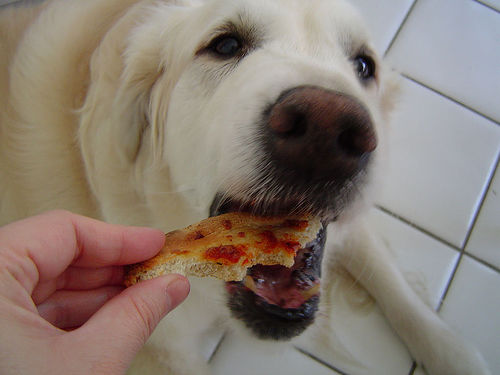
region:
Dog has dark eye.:
[193, 28, 255, 72]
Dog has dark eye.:
[338, 43, 383, 80]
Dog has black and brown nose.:
[295, 89, 354, 151]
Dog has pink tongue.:
[263, 273, 311, 325]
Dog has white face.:
[203, 106, 239, 156]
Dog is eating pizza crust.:
[183, 211, 268, 273]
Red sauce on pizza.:
[210, 240, 249, 268]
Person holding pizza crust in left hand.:
[72, 195, 189, 366]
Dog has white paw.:
[381, 299, 488, 371]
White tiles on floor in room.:
[416, 202, 463, 294]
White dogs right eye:
[350, 44, 380, 86]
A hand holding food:
[0, 210, 188, 372]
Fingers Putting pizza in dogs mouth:
[130, 193, 328, 340]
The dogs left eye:
[205, 28, 247, 66]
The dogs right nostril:
[335, 117, 365, 157]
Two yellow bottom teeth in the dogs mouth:
[245, 270, 320, 295]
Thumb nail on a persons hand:
[160, 275, 190, 305]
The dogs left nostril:
[276, 101, 307, 138]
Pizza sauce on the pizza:
[196, 219, 300, 271]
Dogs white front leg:
[390, 321, 493, 373]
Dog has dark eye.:
[197, 28, 244, 60]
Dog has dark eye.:
[343, 45, 387, 87]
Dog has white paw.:
[413, 309, 455, 362]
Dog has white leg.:
[346, 232, 370, 254]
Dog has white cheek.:
[191, 115, 221, 152]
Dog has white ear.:
[95, 46, 156, 111]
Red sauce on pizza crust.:
[208, 247, 255, 273]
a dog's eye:
[200, 28, 246, 61]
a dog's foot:
[353, 248, 491, 373]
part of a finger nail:
[166, 278, 186, 304]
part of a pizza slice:
[174, 227, 301, 265]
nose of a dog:
[257, 86, 375, 179]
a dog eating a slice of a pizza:
[190, 0, 400, 344]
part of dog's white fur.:
[0, 35, 77, 210]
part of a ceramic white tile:
[413, 95, 498, 255]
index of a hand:
[7, 205, 165, 268]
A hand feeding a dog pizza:
[55, 2, 404, 367]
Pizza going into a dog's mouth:
[189, 193, 342, 341]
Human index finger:
[6, 196, 168, 260]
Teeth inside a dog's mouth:
[240, 271, 331, 301]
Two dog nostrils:
[266, 76, 373, 206]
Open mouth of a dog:
[199, 169, 350, 349]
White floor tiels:
[399, 13, 499, 260]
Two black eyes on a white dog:
[184, 13, 402, 89]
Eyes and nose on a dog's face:
[169, 6, 401, 166]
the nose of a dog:
[242, 95, 374, 183]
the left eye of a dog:
[200, 24, 260, 74]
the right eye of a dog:
[316, 38, 389, 86]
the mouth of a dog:
[221, 144, 333, 338]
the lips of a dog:
[234, 298, 295, 345]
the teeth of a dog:
[237, 271, 324, 311]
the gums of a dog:
[257, 271, 292, 300]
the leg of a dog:
[332, 239, 479, 374]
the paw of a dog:
[408, 330, 491, 370]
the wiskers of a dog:
[229, 177, 292, 208]